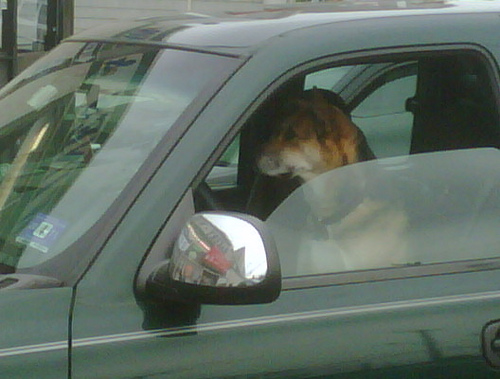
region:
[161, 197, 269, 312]
reflection on car side mirror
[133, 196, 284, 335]
silver and black car mirror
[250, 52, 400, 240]
dog in a car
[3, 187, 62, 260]
blue and white sticker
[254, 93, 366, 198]
brown and white dog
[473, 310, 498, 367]
handle of a car door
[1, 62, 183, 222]
front window of a car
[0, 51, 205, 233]
reflection on front car window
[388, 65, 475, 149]
seat buckle part in car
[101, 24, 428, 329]
dog in drivers seat of car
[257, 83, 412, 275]
dog sitting in front of a automobile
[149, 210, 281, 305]
black and silver rear view mirror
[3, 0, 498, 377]
parked green car with a dog inside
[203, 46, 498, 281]
window down on left side of green car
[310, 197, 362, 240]
collar around the dog's neck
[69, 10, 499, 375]
left door on green car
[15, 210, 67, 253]
registration sticker on the car's windshield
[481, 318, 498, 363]
the edge of the door latch on green automobile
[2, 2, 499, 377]
dog sitting in a green car with window halfway down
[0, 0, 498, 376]
dog sitting in car waiting for the pet owner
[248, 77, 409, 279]
dog in the driver's seat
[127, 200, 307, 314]
side view mirror with reflection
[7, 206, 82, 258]
registration decal on a car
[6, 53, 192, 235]
vehicle windshield with reflections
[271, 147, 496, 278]
partially open car window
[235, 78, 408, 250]
dog with a collar in the car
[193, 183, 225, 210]
steering wheel in front of the dog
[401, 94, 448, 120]
shoulder seat belt strap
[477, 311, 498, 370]
outside door handle to car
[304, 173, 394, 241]
collar belonging to a dog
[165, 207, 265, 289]
reflection in a chromed sideview mirror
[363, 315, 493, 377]
reflection of power lines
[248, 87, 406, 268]
a dog left in the driver's seat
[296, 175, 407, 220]
a dog's collar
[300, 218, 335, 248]
tags to identify dog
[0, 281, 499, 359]
pin stripe on side of vehicle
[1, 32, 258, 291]
a vehicle's windshield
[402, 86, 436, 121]
buckle of a seat belt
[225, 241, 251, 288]
pointed top of a steeple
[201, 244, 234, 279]
red door awning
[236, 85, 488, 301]
A dog is in the drivers seat.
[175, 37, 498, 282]
The car window is down.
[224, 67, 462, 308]
The dog is brown and white.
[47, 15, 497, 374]
The car is green.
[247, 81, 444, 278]
The dog is content.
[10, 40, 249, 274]
A window is in the car.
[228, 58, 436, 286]
The dog is looking out the front window.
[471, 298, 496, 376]
The car door handle is black.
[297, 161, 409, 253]
The dog is wearing a collar.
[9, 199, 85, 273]
A sticker is on the windshield.